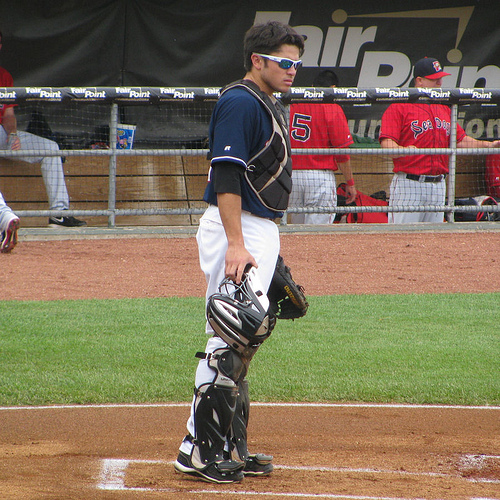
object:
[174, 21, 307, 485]
man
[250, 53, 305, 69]
sunglasses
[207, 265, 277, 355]
helmet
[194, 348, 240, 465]
knee and shin pads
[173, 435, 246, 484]
sneakers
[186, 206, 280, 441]
pants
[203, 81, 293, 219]
black vest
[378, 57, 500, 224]
man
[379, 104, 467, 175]
red baseball shirt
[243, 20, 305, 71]
dark brown hair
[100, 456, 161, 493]
white lines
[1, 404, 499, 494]
dirt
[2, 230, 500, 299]
red clay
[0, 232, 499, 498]
baseball field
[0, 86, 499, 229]
chainlink fence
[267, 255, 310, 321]
baseball glove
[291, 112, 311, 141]
black number 5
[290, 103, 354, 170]
baseball jersey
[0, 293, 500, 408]
green grass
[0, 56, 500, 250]
players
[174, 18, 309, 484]
catcher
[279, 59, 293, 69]
silver frame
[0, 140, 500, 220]
wooden bench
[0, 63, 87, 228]
baseball player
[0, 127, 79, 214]
gray pants